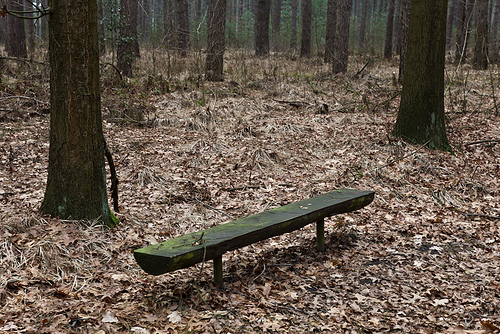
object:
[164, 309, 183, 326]
leaves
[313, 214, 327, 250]
leg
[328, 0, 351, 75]
tree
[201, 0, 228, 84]
tree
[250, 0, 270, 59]
tree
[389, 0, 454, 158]
trunk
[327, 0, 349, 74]
trunk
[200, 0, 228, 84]
trunk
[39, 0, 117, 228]
trunk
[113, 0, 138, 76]
trees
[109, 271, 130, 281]
leaves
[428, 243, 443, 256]
leaves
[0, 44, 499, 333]
grass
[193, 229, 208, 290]
twig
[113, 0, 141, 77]
trunk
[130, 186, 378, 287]
wooden bench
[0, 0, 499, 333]
forest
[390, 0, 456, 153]
tree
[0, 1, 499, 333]
park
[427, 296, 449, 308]
leaves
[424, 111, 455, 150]
moss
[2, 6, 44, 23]
branch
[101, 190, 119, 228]
moss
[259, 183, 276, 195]
leaves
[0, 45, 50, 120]
brush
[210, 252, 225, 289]
chair stand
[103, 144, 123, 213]
branch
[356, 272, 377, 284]
leaves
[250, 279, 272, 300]
leaves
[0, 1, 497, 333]
background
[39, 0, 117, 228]
tree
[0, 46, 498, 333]
floor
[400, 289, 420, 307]
leaves